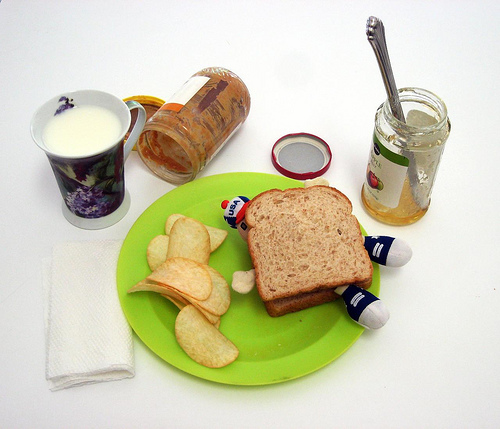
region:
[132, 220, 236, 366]
several Pringles potato chips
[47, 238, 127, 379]
white napkin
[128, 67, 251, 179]
empty jar of peanut butter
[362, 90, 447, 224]
empty jar of jelly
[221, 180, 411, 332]
USA doll between two slices of wheat bread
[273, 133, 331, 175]
jelly jar lid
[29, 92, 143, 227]
coffee mug full of milk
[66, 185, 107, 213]
purple flowers on the side of a mug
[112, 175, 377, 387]
green plate with a sandwich and chips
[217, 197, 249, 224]
red white a blue hat on a doll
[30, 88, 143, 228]
Mug filled with milk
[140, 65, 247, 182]
Almost empty peanut butter can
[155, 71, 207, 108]
Label on the peanut butter can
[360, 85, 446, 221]
Almost empty jam can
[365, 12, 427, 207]
Knife in the jam can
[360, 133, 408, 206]
Label on the jam can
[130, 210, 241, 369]
Chips on the green plate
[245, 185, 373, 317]
Bread on the plate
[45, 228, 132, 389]
Napkin next to the plate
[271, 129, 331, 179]
Jam can cap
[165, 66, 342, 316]
the glass is empty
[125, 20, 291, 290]
the glass is empty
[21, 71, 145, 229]
tall cup of milk on a white table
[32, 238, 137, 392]
white napkin on a table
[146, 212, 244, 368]
potato chips on a green plate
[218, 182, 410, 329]
a manwich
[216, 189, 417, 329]
toy between two slice of bread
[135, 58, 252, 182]
empty peanut butter jar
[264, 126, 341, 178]
red lid on a table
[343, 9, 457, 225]
silver knife in an empty jar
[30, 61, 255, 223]
cup of milk and empty jar on a table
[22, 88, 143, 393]
napkin and tall cup of milk on a table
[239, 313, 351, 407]
The plate is green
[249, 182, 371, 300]
A slice of bread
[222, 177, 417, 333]
A doll is in the sandwich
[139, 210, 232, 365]
Potato chips are on the plate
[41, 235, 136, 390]
A napkin is beside the plate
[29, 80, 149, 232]
A mug of milk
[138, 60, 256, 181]
A peanut butter jar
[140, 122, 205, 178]
The jar is empty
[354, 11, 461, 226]
A butter knife is in this jar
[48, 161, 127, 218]
The mug has a flower design on it